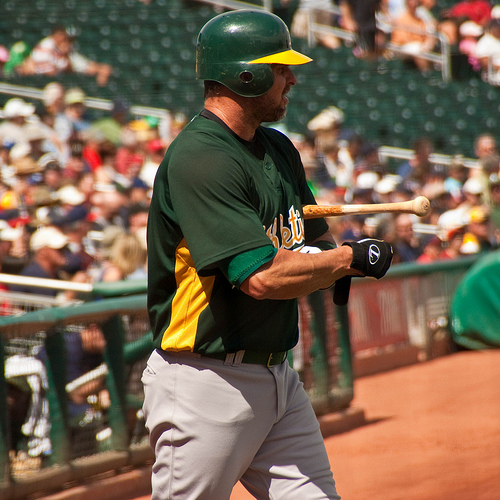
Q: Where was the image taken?
A: It was taken at the stadium.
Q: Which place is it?
A: It is a stadium.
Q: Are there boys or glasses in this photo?
A: No, there are no boys or glasses.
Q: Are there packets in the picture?
A: No, there are no packets.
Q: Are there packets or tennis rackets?
A: No, there are no packets or tennis rackets.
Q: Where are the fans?
A: The fans are in the stadium.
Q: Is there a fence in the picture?
A: Yes, there is a fence.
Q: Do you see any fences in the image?
A: Yes, there is a fence.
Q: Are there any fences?
A: Yes, there is a fence.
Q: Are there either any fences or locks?
A: Yes, there is a fence.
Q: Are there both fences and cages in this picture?
A: No, there is a fence but no cages.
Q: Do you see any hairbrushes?
A: No, there are no hairbrushes.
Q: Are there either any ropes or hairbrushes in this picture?
A: No, there are no hairbrushes or ropes.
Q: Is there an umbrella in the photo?
A: No, there are no umbrellas.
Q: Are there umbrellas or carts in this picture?
A: No, there are no umbrellas or carts.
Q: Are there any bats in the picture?
A: Yes, there is a bat.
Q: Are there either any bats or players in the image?
A: Yes, there is a bat.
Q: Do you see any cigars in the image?
A: No, there are no cigars.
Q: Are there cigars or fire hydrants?
A: No, there are no cigars or fire hydrants.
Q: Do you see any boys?
A: No, there are no boys.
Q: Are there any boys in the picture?
A: No, there are no boys.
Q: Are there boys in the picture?
A: No, there are no boys.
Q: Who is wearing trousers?
A: The man is wearing trousers.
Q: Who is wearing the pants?
A: The man is wearing trousers.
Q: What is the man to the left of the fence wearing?
A: The man is wearing trousers.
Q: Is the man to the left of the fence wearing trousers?
A: Yes, the man is wearing trousers.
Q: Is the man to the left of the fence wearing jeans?
A: No, the man is wearing trousers.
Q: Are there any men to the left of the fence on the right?
A: Yes, there is a man to the left of the fence.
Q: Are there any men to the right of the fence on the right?
A: No, the man is to the left of the fence.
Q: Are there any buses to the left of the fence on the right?
A: No, there is a man to the left of the fence.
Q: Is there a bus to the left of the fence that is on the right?
A: No, there is a man to the left of the fence.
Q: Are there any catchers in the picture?
A: No, there are no catchers.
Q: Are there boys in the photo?
A: No, there are no boys.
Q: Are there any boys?
A: No, there are no boys.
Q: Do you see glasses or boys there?
A: No, there are no boys or glasses.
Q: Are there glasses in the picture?
A: No, there are no glasses.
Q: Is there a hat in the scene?
A: Yes, there is a hat.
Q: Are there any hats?
A: Yes, there is a hat.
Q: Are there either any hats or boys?
A: Yes, there is a hat.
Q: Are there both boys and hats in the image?
A: No, there is a hat but no boys.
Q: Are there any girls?
A: No, there are no girls.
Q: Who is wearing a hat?
A: The man is wearing a hat.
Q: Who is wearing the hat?
A: The man is wearing a hat.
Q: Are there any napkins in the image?
A: No, there are no napkins.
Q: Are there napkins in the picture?
A: No, there are no napkins.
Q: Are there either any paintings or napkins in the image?
A: No, there are no napkins or paintings.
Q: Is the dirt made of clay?
A: Yes, the dirt is made of clay.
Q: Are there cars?
A: No, there are no cars.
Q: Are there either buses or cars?
A: No, there are no cars or buses.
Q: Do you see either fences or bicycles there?
A: Yes, there is a fence.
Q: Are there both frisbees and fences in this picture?
A: No, there is a fence but no frisbees.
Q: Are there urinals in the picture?
A: No, there are no urinals.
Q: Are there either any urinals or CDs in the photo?
A: No, there are no urinals or cds.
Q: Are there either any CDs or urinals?
A: No, there are no urinals or cds.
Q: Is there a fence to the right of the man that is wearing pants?
A: Yes, there is a fence to the right of the man.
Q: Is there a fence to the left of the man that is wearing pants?
A: No, the fence is to the right of the man.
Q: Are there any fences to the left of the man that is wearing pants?
A: No, the fence is to the right of the man.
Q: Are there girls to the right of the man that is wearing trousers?
A: No, there is a fence to the right of the man.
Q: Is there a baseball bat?
A: Yes, there is a baseball bat.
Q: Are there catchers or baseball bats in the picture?
A: Yes, there is a baseball bat.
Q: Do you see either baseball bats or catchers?
A: Yes, there is a baseball bat.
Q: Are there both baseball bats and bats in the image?
A: Yes, there are both a baseball bat and a bat.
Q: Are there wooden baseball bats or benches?
A: Yes, there is a wood baseball bat.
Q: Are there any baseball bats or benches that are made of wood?
A: Yes, the baseball bat is made of wood.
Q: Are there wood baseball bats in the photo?
A: Yes, there is a wood baseball bat.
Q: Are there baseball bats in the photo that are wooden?
A: Yes, there is a baseball bat that is wooden.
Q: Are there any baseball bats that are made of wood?
A: Yes, there is a baseball bat that is made of wood.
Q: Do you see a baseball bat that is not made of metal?
A: Yes, there is a baseball bat that is made of wood.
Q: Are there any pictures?
A: No, there are no pictures.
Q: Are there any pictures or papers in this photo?
A: No, there are no pictures or papers.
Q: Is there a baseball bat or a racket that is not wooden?
A: No, there is a baseball bat but it is wooden.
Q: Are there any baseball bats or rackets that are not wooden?
A: No, there is a baseball bat but it is wooden.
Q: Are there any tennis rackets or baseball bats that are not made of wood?
A: No, there is a baseball bat but it is made of wood.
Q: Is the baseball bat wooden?
A: Yes, the baseball bat is wooden.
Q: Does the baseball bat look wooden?
A: Yes, the baseball bat is wooden.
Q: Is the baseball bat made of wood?
A: Yes, the baseball bat is made of wood.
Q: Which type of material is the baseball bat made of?
A: The baseball bat is made of wood.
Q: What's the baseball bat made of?
A: The baseball bat is made of wood.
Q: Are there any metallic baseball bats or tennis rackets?
A: No, there is a baseball bat but it is wooden.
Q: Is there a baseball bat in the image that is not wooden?
A: No, there is a baseball bat but it is wooden.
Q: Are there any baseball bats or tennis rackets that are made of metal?
A: No, there is a baseball bat but it is made of wood.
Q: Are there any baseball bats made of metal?
A: No, there is a baseball bat but it is made of wood.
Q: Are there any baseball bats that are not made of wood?
A: No, there is a baseball bat but it is made of wood.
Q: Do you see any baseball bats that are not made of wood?
A: No, there is a baseball bat but it is made of wood.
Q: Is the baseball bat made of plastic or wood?
A: The baseball bat is made of wood.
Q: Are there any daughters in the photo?
A: No, there are no daughters.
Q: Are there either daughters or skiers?
A: No, there are no daughters or skiers.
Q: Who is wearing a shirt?
A: The man is wearing a shirt.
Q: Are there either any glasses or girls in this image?
A: No, there are no girls or glasses.